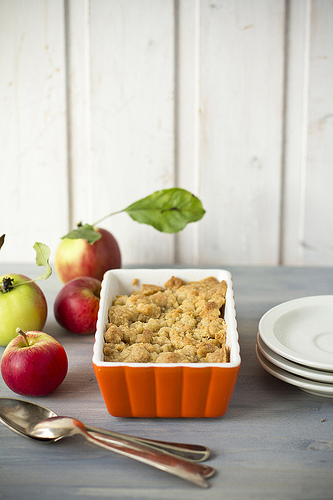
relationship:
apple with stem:
[54, 227, 121, 284] [85, 208, 128, 224]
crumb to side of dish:
[132, 277, 140, 286] [92, 354, 236, 418]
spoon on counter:
[0, 397, 210, 463] [1, 258, 332, 496]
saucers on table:
[250, 289, 331, 397] [1, 255, 331, 499]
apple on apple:
[53, 273, 102, 331] [57, 224, 120, 281]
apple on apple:
[1, 271, 48, 345] [57, 224, 120, 281]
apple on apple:
[4, 328, 70, 396] [57, 224, 120, 281]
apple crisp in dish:
[116, 286, 218, 364] [96, 361, 234, 418]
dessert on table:
[99, 272, 232, 370] [1, 255, 331, 499]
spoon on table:
[0, 397, 210, 463] [0, 259, 331, 500]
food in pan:
[110, 274, 229, 359] [87, 263, 243, 422]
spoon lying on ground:
[0, 394, 220, 491] [0, 260, 332, 498]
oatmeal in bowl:
[107, 273, 229, 358] [92, 267, 240, 415]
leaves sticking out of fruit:
[123, 186, 207, 234] [56, 225, 121, 291]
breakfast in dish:
[106, 277, 228, 361] [110, 228, 215, 384]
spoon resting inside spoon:
[0, 397, 210, 463] [1, 398, 212, 467]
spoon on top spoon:
[0, 397, 210, 463] [0, 397, 210, 463]